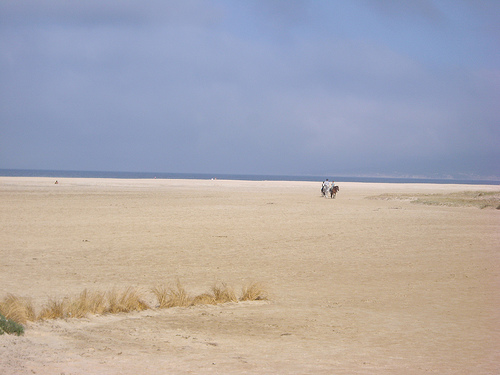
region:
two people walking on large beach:
[306, 174, 339, 196]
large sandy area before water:
[28, 168, 333, 361]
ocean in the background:
[25, 154, 494, 205]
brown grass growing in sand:
[35, 271, 282, 308]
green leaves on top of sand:
[0, 318, 23, 334]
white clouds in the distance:
[320, 156, 424, 184]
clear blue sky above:
[48, 15, 497, 152]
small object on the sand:
[43, 179, 65, 191]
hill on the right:
[343, 166, 498, 241]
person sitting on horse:
[325, 187, 346, 205]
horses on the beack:
[317, 180, 340, 202]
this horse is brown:
[329, 184, 339, 201]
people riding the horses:
[322, 179, 336, 189]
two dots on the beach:
[209, 176, 219, 180]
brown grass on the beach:
[2, 273, 267, 326]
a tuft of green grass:
[0, 312, 29, 338]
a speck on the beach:
[52, 177, 60, 187]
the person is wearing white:
[319, 179, 332, 188]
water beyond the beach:
[0, 162, 477, 184]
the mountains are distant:
[322, 168, 499, 183]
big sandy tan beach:
[24, 189, 177, 273]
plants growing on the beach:
[1, 262, 298, 340]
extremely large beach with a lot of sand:
[1, 161, 496, 360]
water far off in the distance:
[2, 155, 494, 186]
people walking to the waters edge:
[312, 176, 345, 206]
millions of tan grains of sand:
[131, 185, 286, 267]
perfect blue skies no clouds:
[46, 66, 374, 146]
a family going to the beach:
[312, 174, 353, 204]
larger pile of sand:
[367, 181, 499, 232]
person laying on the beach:
[38, 173, 68, 193]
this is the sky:
[230, 8, 390, 115]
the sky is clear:
[260, 20, 397, 122]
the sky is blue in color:
[217, 13, 416, 139]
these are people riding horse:
[315, 175, 340, 196]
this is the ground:
[309, 215, 449, 367]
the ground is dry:
[321, 223, 438, 371]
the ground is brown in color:
[299, 235, 455, 373]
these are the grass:
[212, 281, 254, 306]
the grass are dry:
[182, 284, 229, 306]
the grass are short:
[160, 282, 190, 307]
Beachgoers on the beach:
[317, 178, 342, 203]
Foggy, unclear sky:
[0, 0, 498, 184]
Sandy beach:
[0, 179, 497, 373]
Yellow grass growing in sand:
[2, 275, 273, 334]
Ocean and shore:
[0, 163, 499, 188]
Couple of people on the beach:
[317, 178, 340, 200]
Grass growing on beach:
[0, 275, 275, 337]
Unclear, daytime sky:
[0, 0, 498, 182]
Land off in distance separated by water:
[272, 148, 498, 184]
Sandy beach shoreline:
[1, 163, 498, 185]